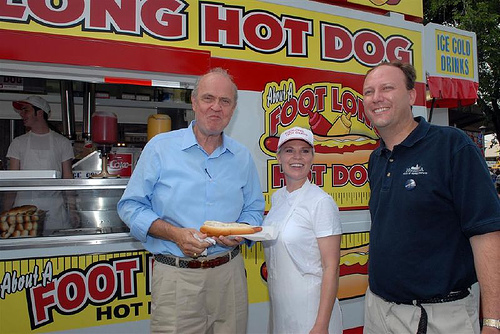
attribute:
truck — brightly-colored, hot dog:
[0, 3, 480, 331]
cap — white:
[276, 127, 314, 145]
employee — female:
[260, 127, 360, 332]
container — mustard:
[146, 111, 172, 140]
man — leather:
[112, 67, 266, 330]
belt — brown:
[156, 245, 241, 267]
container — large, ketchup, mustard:
[93, 112, 121, 178]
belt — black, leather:
[439, 287, 467, 314]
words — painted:
[199, 13, 383, 91]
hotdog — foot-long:
[190, 203, 263, 254]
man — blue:
[120, 75, 272, 314]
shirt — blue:
[362, 113, 497, 303]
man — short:
[151, 55, 258, 175]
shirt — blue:
[130, 120, 277, 270]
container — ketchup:
[83, 97, 126, 146]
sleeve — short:
[340, 130, 497, 302]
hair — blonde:
[190, 68, 240, 98]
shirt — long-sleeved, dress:
[118, 110, 265, 260]